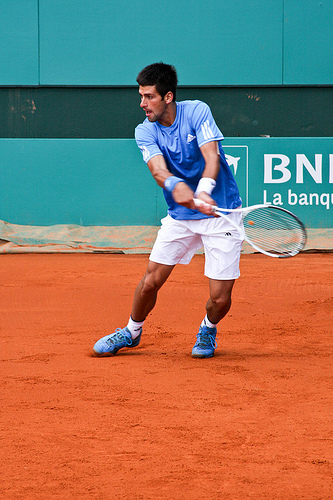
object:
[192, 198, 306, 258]
racket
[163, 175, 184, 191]
wrist band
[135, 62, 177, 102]
hair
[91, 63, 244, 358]
man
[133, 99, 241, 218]
shirt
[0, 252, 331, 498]
dirt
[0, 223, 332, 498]
ground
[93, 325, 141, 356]
shoe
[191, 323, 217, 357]
shoe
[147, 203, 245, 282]
shorts